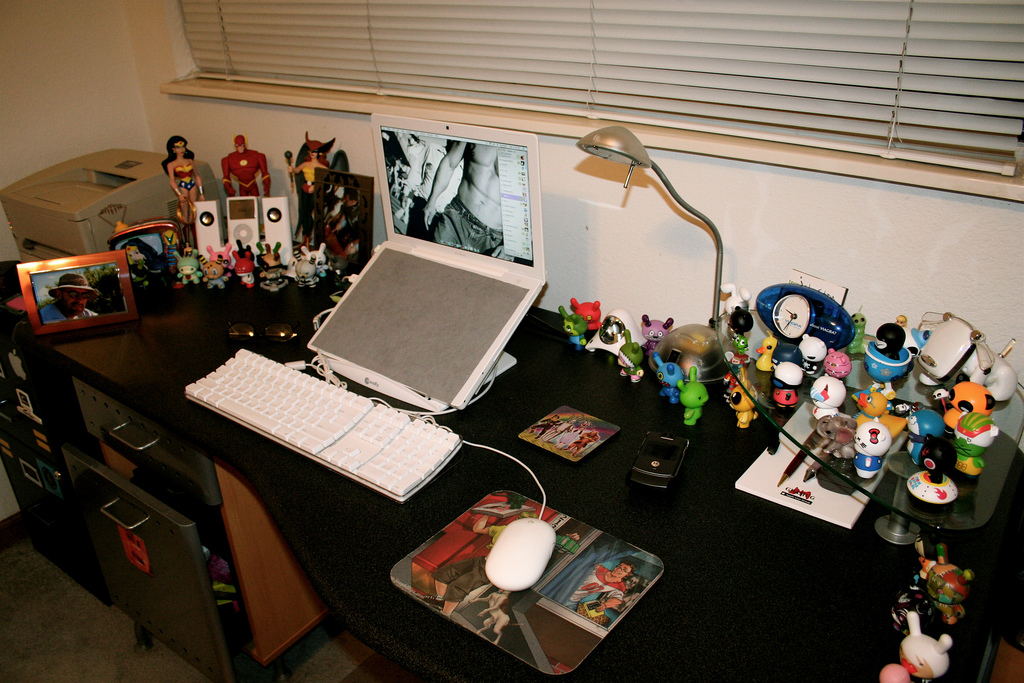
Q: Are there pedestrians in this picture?
A: No, there are no pedestrians.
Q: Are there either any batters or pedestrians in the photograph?
A: No, there are no pedestrians or batters.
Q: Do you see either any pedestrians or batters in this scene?
A: No, there are no pedestrians or batters.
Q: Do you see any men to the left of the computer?
A: Yes, there is a man to the left of the computer.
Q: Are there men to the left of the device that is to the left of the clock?
A: Yes, there is a man to the left of the computer.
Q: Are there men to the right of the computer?
A: No, the man is to the left of the computer.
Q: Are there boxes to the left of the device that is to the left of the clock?
A: No, there is a man to the left of the computer.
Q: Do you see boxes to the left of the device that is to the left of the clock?
A: No, there is a man to the left of the computer.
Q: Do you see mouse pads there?
A: Yes, there is a mouse pad.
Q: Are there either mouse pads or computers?
A: Yes, there is a mouse pad.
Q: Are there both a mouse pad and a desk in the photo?
A: Yes, there are both a mouse pad and a desk.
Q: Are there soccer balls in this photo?
A: No, there are no soccer balls.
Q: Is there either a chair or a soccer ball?
A: No, there are no soccer balls or chairs.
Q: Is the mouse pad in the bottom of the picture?
A: Yes, the mouse pad is in the bottom of the image.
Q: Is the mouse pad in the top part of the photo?
A: No, the mouse pad is in the bottom of the image.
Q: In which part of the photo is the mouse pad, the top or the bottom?
A: The mouse pad is in the bottom of the image.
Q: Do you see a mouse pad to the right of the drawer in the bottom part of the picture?
A: Yes, there is a mouse pad to the right of the drawer.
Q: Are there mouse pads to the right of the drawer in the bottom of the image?
A: Yes, there is a mouse pad to the right of the drawer.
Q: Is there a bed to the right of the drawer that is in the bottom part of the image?
A: No, there is a mouse pad to the right of the drawer.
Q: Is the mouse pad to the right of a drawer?
A: Yes, the mouse pad is to the right of a drawer.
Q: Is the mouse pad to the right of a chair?
A: No, the mouse pad is to the right of a drawer.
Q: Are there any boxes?
A: No, there are no boxes.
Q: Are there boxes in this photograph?
A: No, there are no boxes.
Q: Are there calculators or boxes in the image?
A: No, there are no boxes or calculators.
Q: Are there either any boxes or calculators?
A: No, there are no boxes or calculators.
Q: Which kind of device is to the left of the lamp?
A: The device is a screen.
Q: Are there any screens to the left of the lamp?
A: Yes, there is a screen to the left of the lamp.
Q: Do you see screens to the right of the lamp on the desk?
A: No, the screen is to the left of the lamp.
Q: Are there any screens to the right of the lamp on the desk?
A: No, the screen is to the left of the lamp.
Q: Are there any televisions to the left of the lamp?
A: No, there is a screen to the left of the lamp.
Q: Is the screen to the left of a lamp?
A: Yes, the screen is to the left of a lamp.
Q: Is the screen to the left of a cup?
A: No, the screen is to the left of a lamp.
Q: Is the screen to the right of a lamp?
A: No, the screen is to the left of a lamp.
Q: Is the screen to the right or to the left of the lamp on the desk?
A: The screen is to the left of the lamp.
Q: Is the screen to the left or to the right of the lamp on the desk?
A: The screen is to the left of the lamp.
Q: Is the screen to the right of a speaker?
A: Yes, the screen is to the right of a speaker.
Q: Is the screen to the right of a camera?
A: No, the screen is to the right of a speaker.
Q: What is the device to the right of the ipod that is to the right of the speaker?
A: The device is a screen.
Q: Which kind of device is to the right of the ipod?
A: The device is a screen.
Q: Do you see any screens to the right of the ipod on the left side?
A: Yes, there is a screen to the right of the ipod.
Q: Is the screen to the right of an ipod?
A: Yes, the screen is to the right of an ipod.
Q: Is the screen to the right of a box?
A: No, the screen is to the right of an ipod.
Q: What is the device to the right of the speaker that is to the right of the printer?
A: The device is a screen.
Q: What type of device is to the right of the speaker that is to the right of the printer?
A: The device is a screen.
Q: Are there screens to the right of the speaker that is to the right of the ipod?
A: Yes, there is a screen to the right of the speaker.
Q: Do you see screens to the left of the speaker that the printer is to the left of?
A: No, the screen is to the right of the speaker.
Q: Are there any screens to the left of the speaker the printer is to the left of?
A: No, the screen is to the right of the speaker.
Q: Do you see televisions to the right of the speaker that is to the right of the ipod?
A: No, there is a screen to the right of the speaker.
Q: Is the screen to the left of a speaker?
A: No, the screen is to the right of a speaker.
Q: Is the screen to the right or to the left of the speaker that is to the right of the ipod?
A: The screen is to the right of the speaker.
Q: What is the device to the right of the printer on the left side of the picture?
A: The device is a screen.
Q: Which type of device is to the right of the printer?
A: The device is a screen.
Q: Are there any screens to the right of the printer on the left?
A: Yes, there is a screen to the right of the printer.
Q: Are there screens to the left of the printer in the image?
A: No, the screen is to the right of the printer.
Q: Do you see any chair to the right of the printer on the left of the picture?
A: No, there is a screen to the right of the printer.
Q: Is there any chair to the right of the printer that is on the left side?
A: No, there is a screen to the right of the printer.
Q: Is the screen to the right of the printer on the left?
A: Yes, the screen is to the right of the printer.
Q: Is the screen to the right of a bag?
A: No, the screen is to the right of the printer.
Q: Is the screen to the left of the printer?
A: No, the screen is to the right of the printer.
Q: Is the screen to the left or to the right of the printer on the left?
A: The screen is to the right of the printer.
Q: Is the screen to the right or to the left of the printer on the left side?
A: The screen is to the right of the printer.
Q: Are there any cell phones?
A: Yes, there is a cell phone.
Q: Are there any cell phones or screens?
A: Yes, there is a cell phone.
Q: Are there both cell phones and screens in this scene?
A: Yes, there are both a cell phone and a screen.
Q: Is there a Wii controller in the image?
A: No, there are no Wii controllers.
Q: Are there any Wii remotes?
A: No, there are no Wii remotes.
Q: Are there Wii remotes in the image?
A: No, there are no Wii remotes.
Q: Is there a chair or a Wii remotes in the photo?
A: No, there are no Wii controllers or chairs.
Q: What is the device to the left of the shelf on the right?
A: The device is a cell phone.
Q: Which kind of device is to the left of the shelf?
A: The device is a cell phone.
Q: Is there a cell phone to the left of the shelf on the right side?
A: Yes, there is a cell phone to the left of the shelf.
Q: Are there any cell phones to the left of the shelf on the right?
A: Yes, there is a cell phone to the left of the shelf.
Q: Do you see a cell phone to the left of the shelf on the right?
A: Yes, there is a cell phone to the left of the shelf.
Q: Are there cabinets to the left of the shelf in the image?
A: No, there is a cell phone to the left of the shelf.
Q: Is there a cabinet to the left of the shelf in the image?
A: No, there is a cell phone to the left of the shelf.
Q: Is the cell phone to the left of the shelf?
A: Yes, the cell phone is to the left of the shelf.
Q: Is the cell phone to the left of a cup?
A: No, the cell phone is to the left of the shelf.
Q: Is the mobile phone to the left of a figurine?
A: Yes, the mobile phone is to the left of a figurine.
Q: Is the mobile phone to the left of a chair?
A: No, the mobile phone is to the left of a figurine.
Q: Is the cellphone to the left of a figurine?
A: Yes, the cellphone is to the left of a figurine.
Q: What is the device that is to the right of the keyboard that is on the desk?
A: The device is a cell phone.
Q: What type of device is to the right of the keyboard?
A: The device is a cell phone.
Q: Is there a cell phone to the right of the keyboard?
A: Yes, there is a cell phone to the right of the keyboard.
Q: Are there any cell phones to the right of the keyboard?
A: Yes, there is a cell phone to the right of the keyboard.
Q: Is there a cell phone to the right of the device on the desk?
A: Yes, there is a cell phone to the right of the keyboard.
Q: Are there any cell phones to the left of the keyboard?
A: No, the cell phone is to the right of the keyboard.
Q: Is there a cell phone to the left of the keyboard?
A: No, the cell phone is to the right of the keyboard.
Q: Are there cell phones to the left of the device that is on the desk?
A: No, the cell phone is to the right of the keyboard.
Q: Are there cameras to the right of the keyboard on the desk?
A: No, there is a cell phone to the right of the keyboard.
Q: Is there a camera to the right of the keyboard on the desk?
A: No, there is a cell phone to the right of the keyboard.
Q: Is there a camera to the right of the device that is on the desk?
A: No, there is a cell phone to the right of the keyboard.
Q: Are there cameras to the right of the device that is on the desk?
A: No, there is a cell phone to the right of the keyboard.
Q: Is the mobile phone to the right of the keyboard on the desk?
A: Yes, the mobile phone is to the right of the keyboard.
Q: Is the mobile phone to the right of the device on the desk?
A: Yes, the mobile phone is to the right of the keyboard.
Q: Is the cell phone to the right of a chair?
A: No, the cell phone is to the right of the keyboard.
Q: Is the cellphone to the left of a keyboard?
A: No, the cellphone is to the right of a keyboard.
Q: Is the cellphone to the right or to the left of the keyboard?
A: The cellphone is to the right of the keyboard.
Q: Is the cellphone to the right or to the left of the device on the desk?
A: The cellphone is to the right of the keyboard.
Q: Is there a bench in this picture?
A: No, there are no benches.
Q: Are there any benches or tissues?
A: No, there are no benches or tissues.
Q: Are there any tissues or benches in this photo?
A: No, there are no benches or tissues.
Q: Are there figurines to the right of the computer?
A: Yes, there is a figurine to the right of the computer.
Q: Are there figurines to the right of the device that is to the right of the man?
A: Yes, there is a figurine to the right of the computer.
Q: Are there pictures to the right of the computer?
A: No, there is a figurine to the right of the computer.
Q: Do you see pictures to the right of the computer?
A: No, there is a figurine to the right of the computer.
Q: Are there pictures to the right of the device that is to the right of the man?
A: No, there is a figurine to the right of the computer.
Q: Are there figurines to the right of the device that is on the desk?
A: Yes, there is a figurine to the right of the keyboard.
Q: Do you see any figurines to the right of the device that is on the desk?
A: Yes, there is a figurine to the right of the keyboard.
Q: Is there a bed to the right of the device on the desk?
A: No, there is a figurine to the right of the keyboard.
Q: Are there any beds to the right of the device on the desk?
A: No, there is a figurine to the right of the keyboard.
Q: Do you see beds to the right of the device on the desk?
A: No, there is a figurine to the right of the keyboard.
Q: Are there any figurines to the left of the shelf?
A: Yes, there is a figurine to the left of the shelf.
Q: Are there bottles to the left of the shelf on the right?
A: No, there is a figurine to the left of the shelf.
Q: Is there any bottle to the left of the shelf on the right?
A: No, there is a figurine to the left of the shelf.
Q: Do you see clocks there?
A: Yes, there is a clock.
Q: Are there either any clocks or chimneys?
A: Yes, there is a clock.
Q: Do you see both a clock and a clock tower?
A: No, there is a clock but no clock towers.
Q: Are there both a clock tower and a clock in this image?
A: No, there is a clock but no clock towers.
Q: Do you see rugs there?
A: No, there are no rugs.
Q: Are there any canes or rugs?
A: No, there are no rugs or canes.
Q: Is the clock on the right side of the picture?
A: Yes, the clock is on the right of the image.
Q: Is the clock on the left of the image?
A: No, the clock is on the right of the image.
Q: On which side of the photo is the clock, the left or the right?
A: The clock is on the right of the image.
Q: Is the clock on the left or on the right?
A: The clock is on the right of the image.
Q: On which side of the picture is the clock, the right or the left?
A: The clock is on the right of the image.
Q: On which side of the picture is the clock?
A: The clock is on the right of the image.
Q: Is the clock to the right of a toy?
A: Yes, the clock is to the right of a toy.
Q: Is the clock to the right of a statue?
A: No, the clock is to the right of a toy.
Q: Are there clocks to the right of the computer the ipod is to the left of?
A: Yes, there is a clock to the right of the computer.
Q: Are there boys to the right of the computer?
A: No, there is a clock to the right of the computer.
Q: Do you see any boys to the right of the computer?
A: No, there is a clock to the right of the computer.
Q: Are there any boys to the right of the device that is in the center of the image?
A: No, there is a clock to the right of the computer.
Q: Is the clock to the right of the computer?
A: Yes, the clock is to the right of the computer.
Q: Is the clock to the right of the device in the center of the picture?
A: Yes, the clock is to the right of the computer.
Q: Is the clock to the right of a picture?
A: No, the clock is to the right of the computer.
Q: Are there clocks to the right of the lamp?
A: Yes, there is a clock to the right of the lamp.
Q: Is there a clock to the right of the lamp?
A: Yes, there is a clock to the right of the lamp.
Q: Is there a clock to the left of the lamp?
A: No, the clock is to the right of the lamp.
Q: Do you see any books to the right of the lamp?
A: No, there is a clock to the right of the lamp.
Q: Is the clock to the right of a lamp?
A: Yes, the clock is to the right of a lamp.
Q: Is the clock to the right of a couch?
A: No, the clock is to the right of a lamp.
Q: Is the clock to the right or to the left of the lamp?
A: The clock is to the right of the lamp.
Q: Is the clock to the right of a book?
A: No, the clock is to the right of an action figure.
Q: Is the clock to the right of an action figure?
A: Yes, the clock is to the right of an action figure.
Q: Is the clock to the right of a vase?
A: No, the clock is to the right of an action figure.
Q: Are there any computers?
A: Yes, there is a computer.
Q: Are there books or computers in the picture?
A: Yes, there is a computer.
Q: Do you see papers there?
A: No, there are no papers.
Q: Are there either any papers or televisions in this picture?
A: No, there are no papers or televisions.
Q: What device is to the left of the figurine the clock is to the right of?
A: The device is a computer.